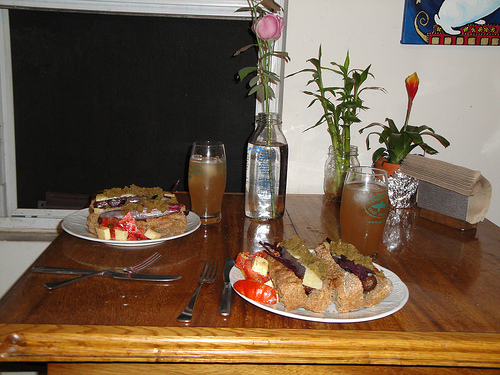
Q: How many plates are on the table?
A: Two.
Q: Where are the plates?
A: Table.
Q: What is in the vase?
A: Flowers.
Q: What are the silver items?
A: Utensils.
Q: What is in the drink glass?
A: Tea.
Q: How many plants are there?
A: Three.